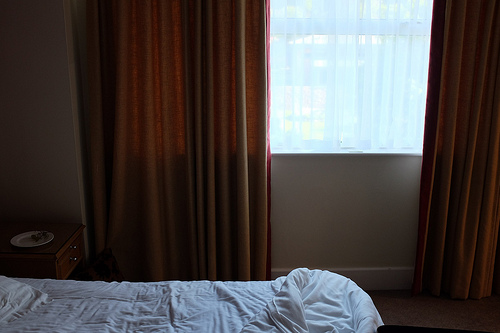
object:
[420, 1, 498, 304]
curtain panel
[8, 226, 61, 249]
white plate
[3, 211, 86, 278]
nightstand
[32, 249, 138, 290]
handles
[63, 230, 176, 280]
drawer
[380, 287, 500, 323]
carpet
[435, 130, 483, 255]
curtain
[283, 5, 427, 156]
man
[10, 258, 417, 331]
blanket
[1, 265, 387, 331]
bed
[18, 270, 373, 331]
sheets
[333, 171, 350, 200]
ground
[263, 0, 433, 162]
white shears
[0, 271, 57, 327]
pillow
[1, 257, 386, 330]
bed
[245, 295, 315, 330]
sheet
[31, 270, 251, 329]
bed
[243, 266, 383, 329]
sheet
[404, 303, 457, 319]
carpet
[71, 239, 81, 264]
knobs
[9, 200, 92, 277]
stand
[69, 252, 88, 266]
knob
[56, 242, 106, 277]
drawer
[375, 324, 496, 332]
edge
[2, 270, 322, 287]
edge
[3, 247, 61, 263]
edge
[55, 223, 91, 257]
edge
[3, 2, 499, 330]
room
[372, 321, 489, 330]
chair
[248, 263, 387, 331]
sheet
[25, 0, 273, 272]
curtain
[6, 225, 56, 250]
plate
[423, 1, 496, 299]
curtain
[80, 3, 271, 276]
curtain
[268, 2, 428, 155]
curtain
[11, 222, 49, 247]
plate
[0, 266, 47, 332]
pillow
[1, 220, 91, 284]
end stand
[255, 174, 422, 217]
wall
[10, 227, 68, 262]
plate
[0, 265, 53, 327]
pillow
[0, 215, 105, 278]
stand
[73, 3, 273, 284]
drapes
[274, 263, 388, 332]
pillow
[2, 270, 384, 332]
blanket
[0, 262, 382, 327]
bed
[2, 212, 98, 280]
night stand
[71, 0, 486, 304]
curtains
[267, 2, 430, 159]
window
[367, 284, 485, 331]
floor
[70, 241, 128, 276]
pillow